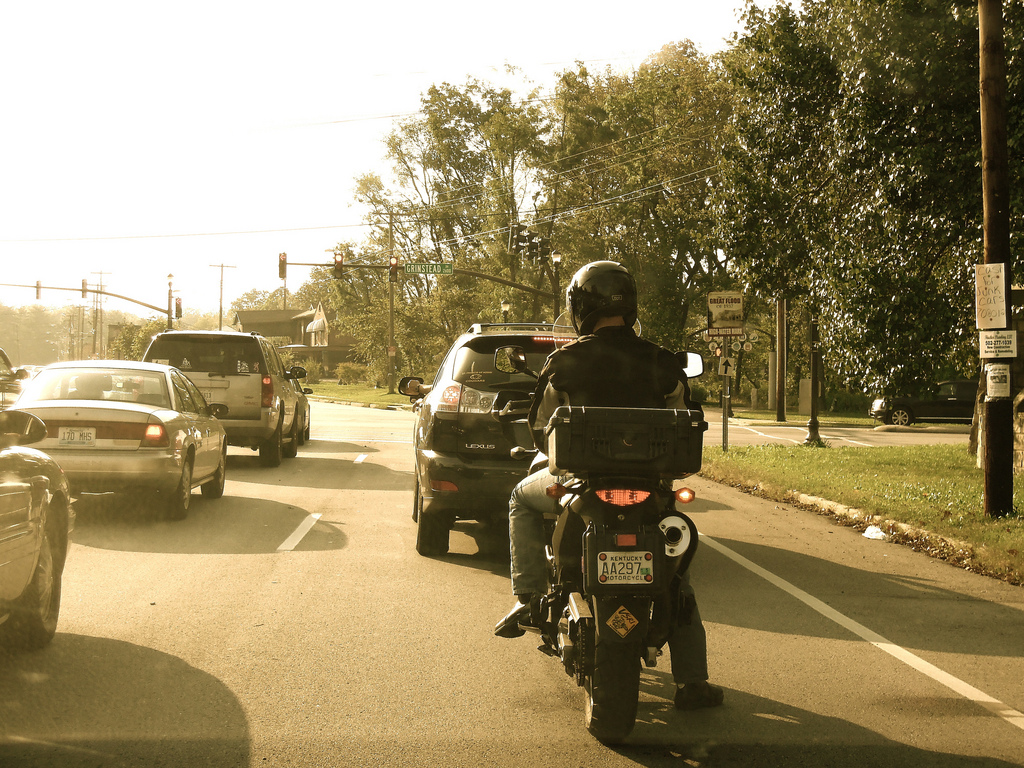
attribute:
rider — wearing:
[495, 262, 727, 708]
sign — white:
[719, 377, 735, 453]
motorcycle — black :
[494, 338, 704, 735]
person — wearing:
[494, 263, 729, 713]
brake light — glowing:
[2, 421, 171, 450]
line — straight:
[678, 526, 1021, 749]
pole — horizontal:
[263, 249, 526, 310]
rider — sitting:
[494, 264, 736, 644]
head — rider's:
[568, 251, 648, 329]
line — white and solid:
[879, 580, 957, 768]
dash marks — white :
[231, 431, 344, 747]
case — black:
[512, 398, 726, 494]